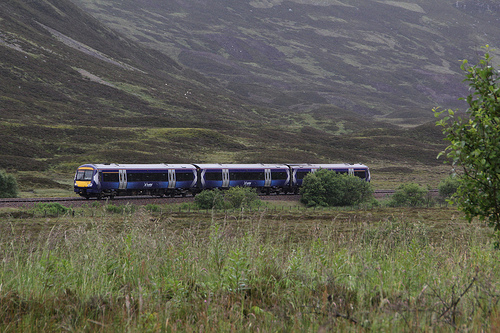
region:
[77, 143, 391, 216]
the train is blue and white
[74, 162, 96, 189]
the front part is yellow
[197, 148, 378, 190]
there are two carts behind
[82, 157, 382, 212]
the train is a passenger train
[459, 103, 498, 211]
the leaves are green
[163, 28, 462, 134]
the surface is hilly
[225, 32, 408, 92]
the hill has patches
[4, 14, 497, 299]
the photo was taken in the daytime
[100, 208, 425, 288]
the grass is tall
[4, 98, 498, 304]
the photo is an outdoor scene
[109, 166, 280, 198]
Blue strip on bottom part of train.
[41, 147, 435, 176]
Train on tracks in grassy area.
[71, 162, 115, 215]
Yellow parts on front of train.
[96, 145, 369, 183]
Train has gray roof.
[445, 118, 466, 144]
Green leaves on tree.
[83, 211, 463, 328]
Tall patch of grass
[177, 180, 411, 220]
Green shrubbery near tracks.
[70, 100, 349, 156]
Hillside in the background.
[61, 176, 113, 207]
Headlights on the front of train.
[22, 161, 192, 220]
Gravel on sides of tracks.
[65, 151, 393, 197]
the train is blue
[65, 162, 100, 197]
front of the train is yellow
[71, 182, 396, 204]
the train is on a track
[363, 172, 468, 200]
this part of the track is empty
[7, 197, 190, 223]
shrubs are growing by the track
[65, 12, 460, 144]
the hill side is steep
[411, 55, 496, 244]
the tree has green leaves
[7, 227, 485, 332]
the grass is tall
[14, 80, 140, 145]
the hill side has brown vegetation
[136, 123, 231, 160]
the hill side has some green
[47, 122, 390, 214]
a long train on a track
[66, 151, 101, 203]
windows on the front of a train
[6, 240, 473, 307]
tall green grass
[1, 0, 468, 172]
a large hill side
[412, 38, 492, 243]
a small green tree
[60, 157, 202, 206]
front car of a train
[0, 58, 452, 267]
a train going through a field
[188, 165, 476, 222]
several bushes growing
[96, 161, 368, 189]
several windows in train cars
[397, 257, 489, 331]
small tree branches on the ground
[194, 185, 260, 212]
bushes in a field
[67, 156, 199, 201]
train car on train tracks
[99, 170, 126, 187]
a window in the side of a train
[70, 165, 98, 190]
front windows on a train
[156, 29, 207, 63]
dirt on the side of a hill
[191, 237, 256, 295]
weeds in a field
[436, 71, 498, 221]
trees in a field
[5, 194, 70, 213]
a set of train tracks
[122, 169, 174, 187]
large window on a train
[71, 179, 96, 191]
yellow stripe on the front of a train